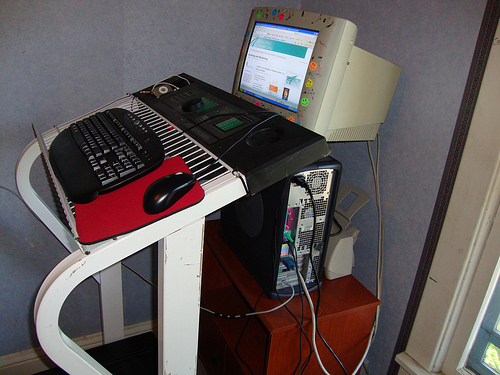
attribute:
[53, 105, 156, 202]
keyboard — close, thick, black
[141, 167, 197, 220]
mouse — red, close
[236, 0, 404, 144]
monitor — wide, on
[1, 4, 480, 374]
wall — blue